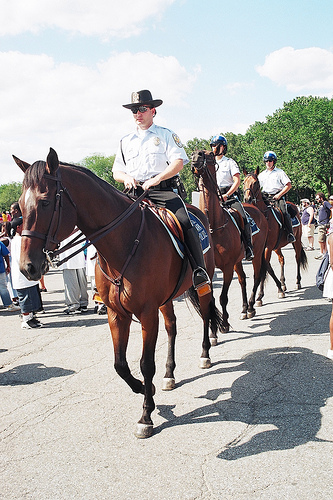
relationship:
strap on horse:
[96, 198, 185, 321] [10, 139, 230, 440]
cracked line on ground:
[192, 303, 328, 499] [0, 234, 333, 499]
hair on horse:
[21, 159, 48, 187] [10, 139, 230, 440]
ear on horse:
[43, 147, 63, 176] [10, 139, 230, 440]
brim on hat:
[146, 98, 163, 106] [122, 90, 163, 110]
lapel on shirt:
[164, 127, 182, 154] [101, 119, 188, 192]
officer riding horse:
[112, 89, 210, 294] [2, 175, 200, 297]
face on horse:
[17, 165, 63, 283] [10, 139, 230, 440]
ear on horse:
[11, 154, 30, 172] [10, 139, 230, 440]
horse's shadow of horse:
[151, 347, 332, 462] [4, 151, 218, 443]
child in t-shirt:
[10, 211, 42, 330] [9, 234, 39, 290]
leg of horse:
[135, 310, 161, 440] [4, 151, 218, 443]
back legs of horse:
[158, 299, 186, 390] [2, 152, 241, 437]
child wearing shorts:
[10, 211, 42, 330] [13, 285, 43, 314]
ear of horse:
[43, 147, 63, 176] [10, 139, 230, 440]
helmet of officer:
[262, 148, 277, 160] [258, 150, 295, 241]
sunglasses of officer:
[131, 104, 146, 113] [112, 89, 210, 294]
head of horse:
[12, 147, 77, 280] [10, 139, 230, 440]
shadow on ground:
[40, 314, 109, 331] [6, 316, 324, 492]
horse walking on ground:
[6, 158, 125, 278] [0, 234, 333, 499]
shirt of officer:
[88, 109, 224, 191] [110, 125, 189, 186]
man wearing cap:
[295, 197, 323, 255] [297, 196, 314, 205]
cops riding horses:
[83, 82, 266, 330] [1, 144, 309, 443]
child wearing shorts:
[10, 211, 42, 330] [12, 281, 41, 315]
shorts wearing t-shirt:
[12, 281, 41, 315] [9, 231, 40, 289]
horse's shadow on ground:
[151, 341, 332, 462] [1, 217, 328, 497]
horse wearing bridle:
[12, 146, 233, 438] [16, 168, 73, 251]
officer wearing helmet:
[257, 150, 296, 242] [262, 147, 277, 159]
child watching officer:
[5, 216, 45, 327] [112, 90, 212, 299]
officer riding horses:
[112, 90, 212, 299] [1, 144, 309, 443]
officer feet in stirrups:
[112, 90, 212, 299] [190, 262, 209, 289]